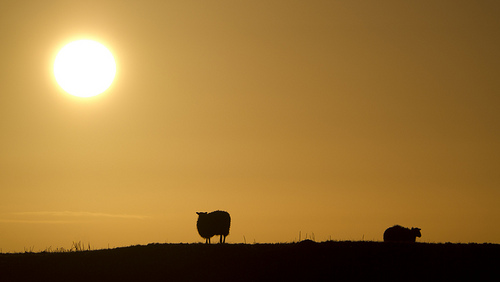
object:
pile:
[300, 239, 315, 243]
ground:
[0, 242, 499, 281]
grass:
[0, 241, 499, 278]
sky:
[0, 0, 499, 253]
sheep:
[383, 224, 421, 242]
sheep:
[195, 210, 231, 244]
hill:
[0, 239, 497, 282]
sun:
[51, 39, 118, 98]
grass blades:
[71, 241, 88, 254]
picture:
[0, 0, 499, 282]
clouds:
[0, 211, 183, 221]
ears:
[416, 227, 418, 229]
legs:
[220, 235, 223, 243]